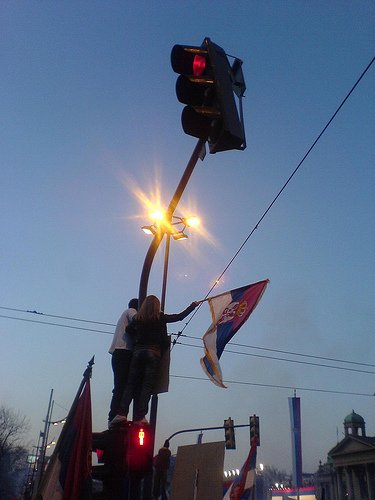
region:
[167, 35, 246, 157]
set of traffic lights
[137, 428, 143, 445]
a human shaped light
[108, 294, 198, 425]
people standing on light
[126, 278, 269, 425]
woman holding a flag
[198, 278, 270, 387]
flag is red blue and white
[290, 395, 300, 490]
a red blue and white banner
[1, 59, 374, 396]
cables in the air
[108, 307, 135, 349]
the shirt is white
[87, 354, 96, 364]
spike on flag pole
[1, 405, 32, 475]
no leaves on the tree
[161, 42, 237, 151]
red signal light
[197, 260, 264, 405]
flag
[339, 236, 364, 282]
white clouds in blue sky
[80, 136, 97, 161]
white clouds in blue sky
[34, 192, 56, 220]
white clouds in blue sky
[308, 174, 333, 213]
white clouds in blue sky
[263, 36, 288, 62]
white clouds in blue sky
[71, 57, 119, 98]
white clouds in blue sky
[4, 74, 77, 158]
white clouds in blue sky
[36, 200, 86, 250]
white clouds in blue sky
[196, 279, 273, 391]
Flag held by the lady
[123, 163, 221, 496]
Night light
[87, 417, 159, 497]
Traffic light on the side of the road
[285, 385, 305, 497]
Tall building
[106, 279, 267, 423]
Group of people on top of the building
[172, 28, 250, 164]
Traffic light on top of the road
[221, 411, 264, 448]
Couple of traffic lights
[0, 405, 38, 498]
Several trees on the side of the road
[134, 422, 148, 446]
Icon from the traffic signal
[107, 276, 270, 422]
Group of people protesting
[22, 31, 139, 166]
Large body of the sky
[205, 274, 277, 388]
A flag is waving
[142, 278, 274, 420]
A lady is holding a flag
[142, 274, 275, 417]
A woman is waving the flag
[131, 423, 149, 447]
The "Do Not Walk" sign is lit up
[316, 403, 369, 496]
Building to the right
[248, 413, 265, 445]
Back of a streetlight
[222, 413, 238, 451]
Back of a street light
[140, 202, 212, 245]
Street lights are turned on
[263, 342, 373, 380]
Power lines in the air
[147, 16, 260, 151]
A traffic light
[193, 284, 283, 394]
A flag in the air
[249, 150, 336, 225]
a power cable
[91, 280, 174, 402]
A man and woman standing on top of traffic light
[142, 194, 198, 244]
Street lights in the photo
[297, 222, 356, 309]
blue clear skies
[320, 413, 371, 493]
A building in the background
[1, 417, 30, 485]
Trees growing in the background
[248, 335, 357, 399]
Power cables in the air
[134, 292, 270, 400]
A woman holding a flag